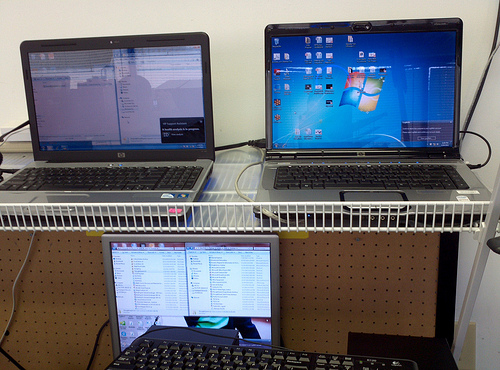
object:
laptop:
[1, 31, 215, 221]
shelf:
[2, 152, 494, 234]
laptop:
[252, 16, 499, 221]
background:
[32, 52, 203, 144]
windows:
[111, 51, 205, 147]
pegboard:
[1, 221, 439, 369]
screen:
[111, 240, 273, 354]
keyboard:
[107, 338, 422, 369]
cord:
[462, 2, 499, 169]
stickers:
[160, 193, 187, 215]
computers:
[4, 18, 493, 360]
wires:
[212, 139, 305, 228]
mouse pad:
[28, 194, 90, 210]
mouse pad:
[343, 190, 407, 214]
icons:
[304, 36, 334, 105]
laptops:
[1, 18, 240, 215]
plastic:
[187, 154, 273, 227]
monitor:
[103, 231, 282, 363]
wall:
[1, 3, 500, 185]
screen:
[273, 36, 456, 147]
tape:
[85, 225, 309, 239]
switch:
[454, 321, 476, 369]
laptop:
[102, 229, 281, 361]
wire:
[2, 230, 110, 369]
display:
[3, 126, 499, 369]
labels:
[456, 188, 481, 206]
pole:
[451, 165, 500, 363]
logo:
[337, 66, 387, 117]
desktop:
[249, 15, 499, 218]